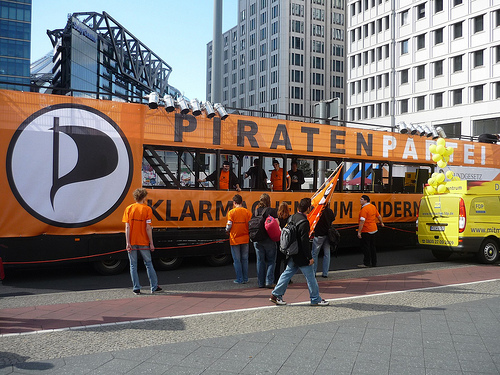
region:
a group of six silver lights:
[141, 89, 246, 121]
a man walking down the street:
[268, 195, 333, 309]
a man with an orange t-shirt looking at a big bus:
[117, 185, 170, 297]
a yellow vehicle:
[416, 178, 498, 270]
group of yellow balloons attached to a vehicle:
[410, 134, 464, 202]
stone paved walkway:
[185, 317, 490, 371]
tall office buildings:
[200, 2, 499, 126]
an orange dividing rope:
[0, 247, 122, 266]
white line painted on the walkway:
[4, 305, 276, 342]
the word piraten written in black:
[161, 107, 376, 163]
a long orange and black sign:
[16, 54, 499, 271]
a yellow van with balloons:
[415, 169, 499, 277]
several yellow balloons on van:
[411, 134, 457, 205]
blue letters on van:
[472, 199, 484, 211]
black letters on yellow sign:
[161, 105, 387, 164]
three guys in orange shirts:
[96, 185, 391, 299]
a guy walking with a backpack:
[248, 182, 352, 317]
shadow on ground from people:
[183, 255, 479, 337]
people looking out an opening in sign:
[144, 136, 379, 194]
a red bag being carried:
[260, 206, 297, 264]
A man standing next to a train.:
[121, 187, 159, 293]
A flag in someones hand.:
[305, 162, 342, 234]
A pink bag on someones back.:
[264, 215, 280, 240]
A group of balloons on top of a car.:
[423, 137, 459, 194]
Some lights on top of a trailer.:
[149, 92, 227, 118]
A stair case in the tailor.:
[141, 147, 183, 187]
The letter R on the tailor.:
[236, 119, 258, 147]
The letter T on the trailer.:
[299, 125, 319, 151]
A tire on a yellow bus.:
[481, 238, 499, 260]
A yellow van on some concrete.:
[418, 188, 499, 261]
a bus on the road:
[54, 58, 465, 263]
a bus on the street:
[76, 36, 482, 318]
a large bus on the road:
[133, 84, 490, 318]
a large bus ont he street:
[112, 71, 428, 341]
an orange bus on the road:
[72, 51, 484, 339]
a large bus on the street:
[64, 64, 493, 356]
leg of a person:
[116, 247, 140, 294]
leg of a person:
[142, 245, 162, 290]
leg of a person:
[225, 242, 242, 279]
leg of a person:
[239, 240, 254, 282]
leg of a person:
[252, 247, 263, 292]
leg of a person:
[260, 239, 276, 295]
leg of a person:
[277, 262, 290, 308]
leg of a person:
[308, 262, 332, 316]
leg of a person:
[308, 231, 320, 271]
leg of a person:
[316, 234, 336, 281]